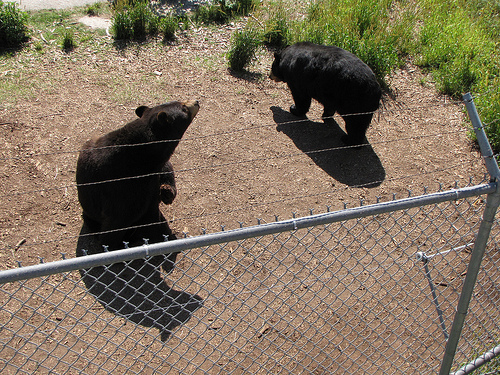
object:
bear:
[263, 41, 381, 149]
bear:
[72, 96, 205, 256]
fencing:
[2, 94, 500, 373]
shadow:
[268, 104, 385, 188]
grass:
[2, 2, 500, 162]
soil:
[0, 37, 498, 373]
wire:
[3, 95, 468, 164]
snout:
[194, 99, 201, 109]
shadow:
[77, 220, 207, 341]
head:
[133, 99, 202, 144]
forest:
[17, 22, 494, 364]